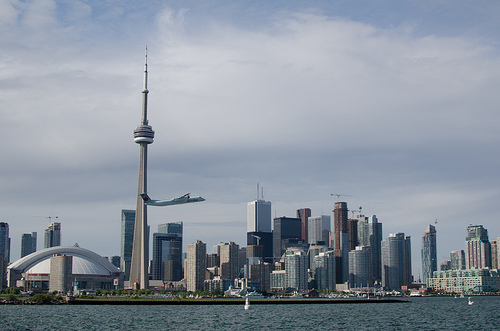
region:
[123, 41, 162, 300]
Space needle in the Toronto skyline.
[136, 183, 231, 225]
Airplane taking off from the airport.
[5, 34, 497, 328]
Toronto skyline from Lake Ontario.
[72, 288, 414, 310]
Pier on the waterside for the docking of boats.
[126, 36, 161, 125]
Spire for modern communications transmission.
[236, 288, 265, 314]
Buoy in the water designating some kind of structure.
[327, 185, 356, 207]
Crane on top of unfinished building.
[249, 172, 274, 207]
Antennae towers on top of the building for communication purposes.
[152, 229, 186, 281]
Modern glass building for sun reflection.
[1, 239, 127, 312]
Baseball stadium for professional competitions.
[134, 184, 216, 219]
low flying white airplane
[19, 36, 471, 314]
city skyline along the water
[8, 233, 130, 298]
rounded top building in the city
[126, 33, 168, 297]
tall skinny building with a spire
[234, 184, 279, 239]
white skyscraper with two needles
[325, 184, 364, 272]
brown circullar building in the city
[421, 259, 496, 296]
low building with many windows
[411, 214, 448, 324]
multi-tiered building near the water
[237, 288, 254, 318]
white buoy bobbing in the water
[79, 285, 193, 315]
grassy area near the water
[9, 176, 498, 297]
skyline of a city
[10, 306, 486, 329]
body of water in front of city skyline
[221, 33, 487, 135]
white clouds in the sky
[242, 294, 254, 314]
buoy in the water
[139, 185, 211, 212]
flag banner waving in the wind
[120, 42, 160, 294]
tallest building in the city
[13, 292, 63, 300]
green bushes by the shore line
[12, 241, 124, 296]
domed building in the distance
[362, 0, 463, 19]
blue sky in the background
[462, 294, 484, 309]
small boat in the water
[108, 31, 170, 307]
futuristic looking building with a spire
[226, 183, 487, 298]
skyline of a city near the water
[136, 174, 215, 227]
low flying airplane over the water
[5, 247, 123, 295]
building with a sloping top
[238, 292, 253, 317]
white floating buoy in the water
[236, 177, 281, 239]
white skyscraper with two needles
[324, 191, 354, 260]
circular brown building in the city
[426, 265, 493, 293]
large low building with many windows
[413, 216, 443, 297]
multi-tiered building in the city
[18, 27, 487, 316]
city skyline near the water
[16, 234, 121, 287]
The domed roof of a building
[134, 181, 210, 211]
A plane taking off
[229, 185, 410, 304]
Tall buildings in a city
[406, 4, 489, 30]
Blue sky above the clouds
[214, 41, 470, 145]
Large clouds in the sky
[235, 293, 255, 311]
A white buoy on the water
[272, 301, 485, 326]
A large body of water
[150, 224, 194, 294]
A tall glass building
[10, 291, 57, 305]
Bushes by the waterside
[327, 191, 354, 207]
An antenna on top of a building